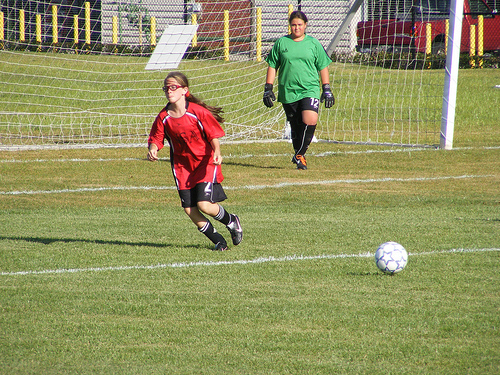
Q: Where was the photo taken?
A: It was taken at the field.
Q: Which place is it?
A: It is a field.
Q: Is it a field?
A: Yes, it is a field.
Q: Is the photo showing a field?
A: Yes, it is showing a field.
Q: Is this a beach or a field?
A: It is a field.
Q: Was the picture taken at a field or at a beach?
A: It was taken at a field.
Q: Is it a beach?
A: No, it is a field.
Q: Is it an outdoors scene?
A: Yes, it is outdoors.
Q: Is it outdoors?
A: Yes, it is outdoors.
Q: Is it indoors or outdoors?
A: It is outdoors.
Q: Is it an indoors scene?
A: No, it is outdoors.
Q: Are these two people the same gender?
A: Yes, all the people are female.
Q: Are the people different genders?
A: No, all the people are female.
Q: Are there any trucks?
A: Yes, there is a truck.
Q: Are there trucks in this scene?
A: Yes, there is a truck.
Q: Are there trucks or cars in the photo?
A: Yes, there is a truck.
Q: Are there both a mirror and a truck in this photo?
A: No, there is a truck but no mirrors.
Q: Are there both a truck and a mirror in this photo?
A: No, there is a truck but no mirrors.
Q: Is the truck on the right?
A: Yes, the truck is on the right of the image.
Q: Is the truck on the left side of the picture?
A: No, the truck is on the right of the image.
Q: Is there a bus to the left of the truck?
A: No, there is a girl to the left of the truck.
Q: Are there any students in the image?
A: No, there are no students.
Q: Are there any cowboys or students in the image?
A: No, there are no students or cowboys.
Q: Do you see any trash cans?
A: No, there are no trash cans.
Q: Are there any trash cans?
A: No, there are no trash cans.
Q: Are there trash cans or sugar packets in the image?
A: No, there are no trash cans or sugar packets.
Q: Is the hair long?
A: Yes, the hair is long.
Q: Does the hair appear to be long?
A: Yes, the hair is long.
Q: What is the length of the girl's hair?
A: The hair is long.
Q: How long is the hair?
A: The hair is long.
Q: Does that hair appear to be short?
A: No, the hair is long.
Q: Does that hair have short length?
A: No, the hair is long.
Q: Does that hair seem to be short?
A: No, the hair is long.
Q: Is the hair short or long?
A: The hair is long.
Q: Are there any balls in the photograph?
A: Yes, there is a ball.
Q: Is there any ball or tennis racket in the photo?
A: Yes, there is a ball.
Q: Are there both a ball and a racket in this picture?
A: No, there is a ball but no rackets.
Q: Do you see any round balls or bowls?
A: Yes, there is a round ball.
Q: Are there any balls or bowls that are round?
A: Yes, the ball is round.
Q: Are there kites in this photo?
A: No, there are no kites.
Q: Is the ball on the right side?
A: Yes, the ball is on the right of the image.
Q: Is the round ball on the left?
A: No, the ball is on the right of the image.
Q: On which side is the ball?
A: The ball is on the right of the image.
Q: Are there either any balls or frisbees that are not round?
A: No, there is a ball but it is round.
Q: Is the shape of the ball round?
A: Yes, the ball is round.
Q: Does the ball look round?
A: Yes, the ball is round.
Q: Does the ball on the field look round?
A: Yes, the ball is round.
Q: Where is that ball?
A: The ball is on the field.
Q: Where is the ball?
A: The ball is on the field.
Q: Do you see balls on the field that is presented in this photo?
A: Yes, there is a ball on the field.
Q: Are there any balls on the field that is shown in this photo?
A: Yes, there is a ball on the field.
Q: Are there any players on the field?
A: No, there is a ball on the field.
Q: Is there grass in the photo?
A: Yes, there is grass.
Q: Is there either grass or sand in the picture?
A: Yes, there is grass.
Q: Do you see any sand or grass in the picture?
A: Yes, there is grass.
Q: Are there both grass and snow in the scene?
A: No, there is grass but no snow.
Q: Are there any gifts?
A: No, there are no gifts.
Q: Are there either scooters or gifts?
A: No, there are no gifts or scooters.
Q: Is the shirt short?
A: Yes, the shirt is short.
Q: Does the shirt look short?
A: Yes, the shirt is short.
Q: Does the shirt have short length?
A: Yes, the shirt is short.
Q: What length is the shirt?
A: The shirt is short.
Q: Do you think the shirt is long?
A: No, the shirt is short.